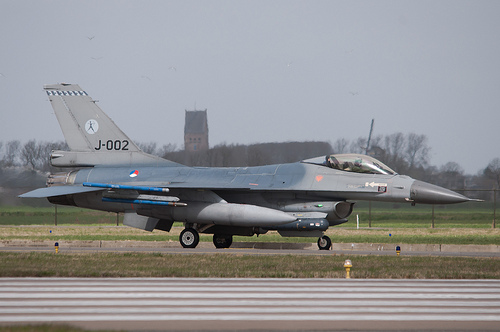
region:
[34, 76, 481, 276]
Military airplane on tarmac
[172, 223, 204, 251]
Airplane tire with white wheel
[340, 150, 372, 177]
Pilot in cockpit of airplane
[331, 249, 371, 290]
Yellow marking on runway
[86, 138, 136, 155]
Identification numbers on airplane tail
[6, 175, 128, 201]
Partial wing of airplane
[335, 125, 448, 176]
Trees with no leaves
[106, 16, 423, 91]
Gray and overcast sky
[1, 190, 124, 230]
Green grass in field by runway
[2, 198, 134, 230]
Fence next to airport runway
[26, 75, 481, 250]
A gray jet airplane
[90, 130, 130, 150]
The letter and number J-002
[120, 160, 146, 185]
A red blue and white decal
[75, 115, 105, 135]
A white circle decal with a figure on it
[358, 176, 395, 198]
An arrow pointing to the back of plane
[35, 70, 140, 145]
Tail of plane with design on tip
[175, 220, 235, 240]
Jet plane back wheels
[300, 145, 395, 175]
Cockpit cover on plane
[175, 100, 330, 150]
Large building in the background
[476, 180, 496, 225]
Fence on the outer edge of landing field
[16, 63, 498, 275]
airplane on the runway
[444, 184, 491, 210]
sharp point on the nose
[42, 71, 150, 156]
tail of the plane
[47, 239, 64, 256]
small pole in the grass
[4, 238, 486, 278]
grass along the runway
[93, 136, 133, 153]
black writing on the plane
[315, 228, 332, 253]
front wheel is down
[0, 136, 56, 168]
tree with no leaves on it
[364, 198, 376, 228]
skinny black pole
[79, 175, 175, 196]
blue rod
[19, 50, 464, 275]
fighter jet on runway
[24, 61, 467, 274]
blue jet on runway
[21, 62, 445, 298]
gray jet on runway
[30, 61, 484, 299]
silver jet on runway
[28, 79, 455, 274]
gray jet with blue wings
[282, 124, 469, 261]
small jet with one seat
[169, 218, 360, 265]
black wheels on jet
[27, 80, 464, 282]
grassy landscape behind airport runway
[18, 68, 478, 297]
blue and gray military plane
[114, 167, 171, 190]
blue, red, and white logo on jet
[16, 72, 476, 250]
gray jet on ground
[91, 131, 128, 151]
identifying letter and numbers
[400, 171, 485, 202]
darker gray pointy nose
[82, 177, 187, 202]
blue poles above and below wings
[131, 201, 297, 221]
oval cylinder to side of fuselage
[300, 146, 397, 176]
glass oval covering pilots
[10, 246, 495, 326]
grey and tan lines next to grass strip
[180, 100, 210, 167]
narrow and tall building behind jet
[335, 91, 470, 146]
bright grey skies, trees and fence behind aircraft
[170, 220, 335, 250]
three black wheels under jet